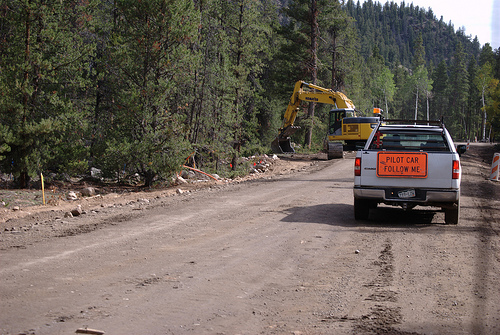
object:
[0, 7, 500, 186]
trees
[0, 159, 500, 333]
road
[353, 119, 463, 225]
truck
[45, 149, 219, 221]
rocks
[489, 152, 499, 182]
barrel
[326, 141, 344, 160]
middle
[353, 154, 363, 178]
tail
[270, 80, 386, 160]
machinery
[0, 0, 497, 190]
hillside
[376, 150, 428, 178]
pilot car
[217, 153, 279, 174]
dirt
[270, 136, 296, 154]
metal bucket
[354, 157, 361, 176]
light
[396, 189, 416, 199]
license plate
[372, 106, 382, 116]
warning light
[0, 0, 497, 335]
daytime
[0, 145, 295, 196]
left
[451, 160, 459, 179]
lights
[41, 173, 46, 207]
pole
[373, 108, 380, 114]
light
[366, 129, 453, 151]
window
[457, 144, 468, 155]
mirror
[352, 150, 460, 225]
back